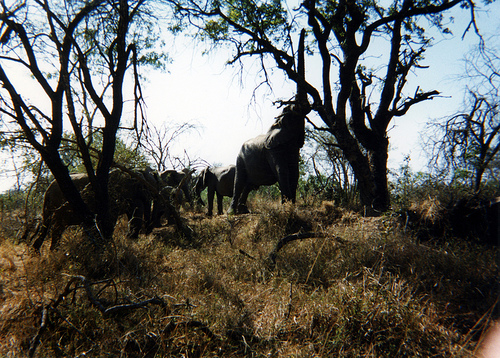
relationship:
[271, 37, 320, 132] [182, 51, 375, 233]
trunk of elephant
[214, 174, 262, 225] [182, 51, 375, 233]
leg of elephant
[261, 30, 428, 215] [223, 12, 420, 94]
tree has branch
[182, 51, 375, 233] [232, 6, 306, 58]
elephant reaching leaves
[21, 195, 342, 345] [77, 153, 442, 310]
tree branches on ground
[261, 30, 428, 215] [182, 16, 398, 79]
tree with branches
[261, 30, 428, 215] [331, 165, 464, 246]
tree and bush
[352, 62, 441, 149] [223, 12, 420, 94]
broken tree branch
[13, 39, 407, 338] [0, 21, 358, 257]
heard of elephants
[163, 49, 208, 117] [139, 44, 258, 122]
sky has clouds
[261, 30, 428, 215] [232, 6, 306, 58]
tree has leaves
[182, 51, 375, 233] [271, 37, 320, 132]
elephant uses trunk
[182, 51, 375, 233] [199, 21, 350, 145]
elephant reaches up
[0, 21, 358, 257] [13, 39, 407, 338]
elephants in background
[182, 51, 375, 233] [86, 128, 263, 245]
elephant on left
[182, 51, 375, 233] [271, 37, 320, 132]
elephant with trunk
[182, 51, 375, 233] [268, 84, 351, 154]
elephant with head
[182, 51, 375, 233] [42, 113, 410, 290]
elephant in field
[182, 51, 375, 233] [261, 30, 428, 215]
elephant under tree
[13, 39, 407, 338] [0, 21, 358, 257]
group of elephants